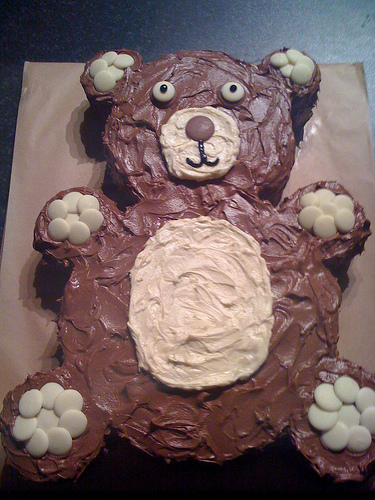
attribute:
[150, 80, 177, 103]
circular chip — white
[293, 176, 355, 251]
chocolate — white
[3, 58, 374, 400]
paper bag — brown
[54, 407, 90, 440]
chip — white, circular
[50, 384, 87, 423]
chip — white, circular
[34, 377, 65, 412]
chip — white, circular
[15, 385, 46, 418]
chip — white, circular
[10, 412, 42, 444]
chip — white, circular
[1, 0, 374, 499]
table — black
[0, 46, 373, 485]
cake — teddy bear, homemade 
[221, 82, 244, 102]
eye — candy 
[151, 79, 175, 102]
eye — candy 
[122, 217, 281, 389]
patch — tan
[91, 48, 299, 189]
cake face — brown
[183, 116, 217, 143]
soccer shoe — chocolate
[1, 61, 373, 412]
board — cake board, tan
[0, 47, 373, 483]
bear — teddy bear, cake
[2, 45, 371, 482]
bear cake — edible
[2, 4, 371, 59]
countertop —  black,  slate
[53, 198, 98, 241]
pieces — chocolate, white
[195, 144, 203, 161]
line — thin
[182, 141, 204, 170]
frosting — black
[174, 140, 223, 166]
mouth — teddy bears mouth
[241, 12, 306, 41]
surface — black